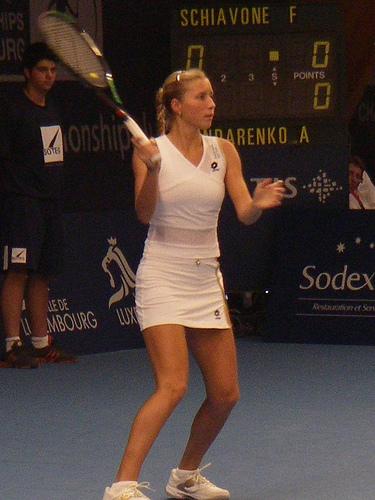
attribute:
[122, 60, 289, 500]
woman — bending knees, playing tennis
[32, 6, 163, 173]
racket — tennis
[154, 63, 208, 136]
hair — braided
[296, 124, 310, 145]
letter — yellow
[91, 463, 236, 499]
shoes — white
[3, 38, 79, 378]
man — standing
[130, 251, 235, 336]
skirt — white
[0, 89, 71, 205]
shirt — dark, black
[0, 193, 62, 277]
shorts — black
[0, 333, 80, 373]
shoes — black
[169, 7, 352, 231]
scoreboard — in background, without points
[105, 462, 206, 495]
socks — white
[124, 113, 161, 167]
handle — white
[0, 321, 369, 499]
tennis court — field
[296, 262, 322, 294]
letter — white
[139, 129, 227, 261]
shirt — white